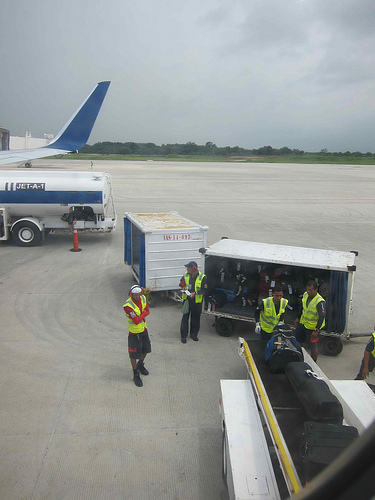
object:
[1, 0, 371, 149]
sky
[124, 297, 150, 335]
man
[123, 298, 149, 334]
clothing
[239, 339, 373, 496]
baggage conveyor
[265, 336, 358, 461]
bags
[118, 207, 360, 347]
baggage trail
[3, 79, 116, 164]
airliner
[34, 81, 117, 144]
wing tip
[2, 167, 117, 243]
fuel tanker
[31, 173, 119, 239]
back end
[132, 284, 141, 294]
cap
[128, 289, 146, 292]
ear muffs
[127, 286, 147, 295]
cap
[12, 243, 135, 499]
concrete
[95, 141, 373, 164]
bushes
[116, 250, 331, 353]
people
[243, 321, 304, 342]
loaded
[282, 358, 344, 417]
luggage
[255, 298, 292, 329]
vest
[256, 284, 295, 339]
man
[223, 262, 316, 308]
luggage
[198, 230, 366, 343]
cart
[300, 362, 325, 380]
tag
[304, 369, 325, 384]
tag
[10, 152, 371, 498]
terminal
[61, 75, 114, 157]
plane's tail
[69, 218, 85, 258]
cone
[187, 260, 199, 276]
headphones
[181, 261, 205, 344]
man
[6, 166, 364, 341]
service vehicles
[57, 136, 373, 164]
distance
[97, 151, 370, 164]
grasses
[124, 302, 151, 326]
employee's arms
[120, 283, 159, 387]
employee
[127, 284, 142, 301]
helmet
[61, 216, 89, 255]
orange cone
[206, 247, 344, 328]
luggage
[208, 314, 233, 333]
tire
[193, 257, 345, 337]
cart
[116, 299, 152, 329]
safety vest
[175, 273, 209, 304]
safety vest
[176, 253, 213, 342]
man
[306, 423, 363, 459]
luggage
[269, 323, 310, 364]
luggage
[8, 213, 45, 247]
wheel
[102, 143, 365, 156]
line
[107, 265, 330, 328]
men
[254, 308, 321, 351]
unloaded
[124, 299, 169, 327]
shirt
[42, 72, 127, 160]
tail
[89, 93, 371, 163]
background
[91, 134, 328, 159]
trees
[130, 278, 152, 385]
man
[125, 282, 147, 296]
hat